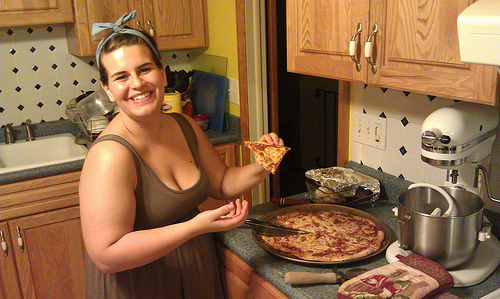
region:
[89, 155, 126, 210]
upper arm on woman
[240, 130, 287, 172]
hand holding the pizza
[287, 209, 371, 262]
part of pizza pie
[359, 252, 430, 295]
an oven mitt on counter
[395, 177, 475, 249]
bottom part of beater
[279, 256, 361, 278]
pizza slicer on counter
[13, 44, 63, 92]
ceramic tile behind sink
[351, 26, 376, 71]
handles on kitchen cabinet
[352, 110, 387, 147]
electrical outlet on wall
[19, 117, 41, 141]
silver faucet on sink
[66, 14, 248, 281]
a woman in a brown dress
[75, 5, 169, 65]
blue hair tie in hair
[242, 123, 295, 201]
one slice of pizza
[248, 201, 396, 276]
a round pan of pizza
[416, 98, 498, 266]
a white mixer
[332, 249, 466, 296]
a decorative oven mitt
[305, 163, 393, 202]
tin foil over container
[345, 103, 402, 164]
white light switches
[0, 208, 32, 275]
white and metal cabinet door pulls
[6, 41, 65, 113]
kitchen wall tiles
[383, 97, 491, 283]
a white mixer on the counter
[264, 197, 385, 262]
a pizza on a pizza pan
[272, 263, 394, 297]
a pizza cutter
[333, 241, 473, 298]
an oven mitt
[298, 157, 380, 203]
a tinfoil covered dish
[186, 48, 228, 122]
cutting boards leaning on a wall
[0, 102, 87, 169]
a white sink in a kitchen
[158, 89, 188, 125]
yellow clorox wipes on a counter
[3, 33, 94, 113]
white with black tile behind a sink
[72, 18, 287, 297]
a woman smiling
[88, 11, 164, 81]
the grey hair tie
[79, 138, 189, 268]
the arm of a woman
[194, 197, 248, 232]
the hand of a woman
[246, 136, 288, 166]
a slice of cheese pizza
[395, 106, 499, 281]
a silver and white blender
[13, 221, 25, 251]
a silver and white handle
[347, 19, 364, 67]
a silver and white handle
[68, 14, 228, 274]
Caucasian woman showing cleavage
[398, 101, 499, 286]
white and shiny chrome mixer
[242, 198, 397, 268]
cheese pizza on round metal pan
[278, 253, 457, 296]
pizza cutter partially covered by potholder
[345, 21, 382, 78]
metal cabinet handles with white trim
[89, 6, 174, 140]
woman wearing blue headband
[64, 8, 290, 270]
woman holding cheese pizza slice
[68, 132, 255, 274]
Caucasian arm bent at elbow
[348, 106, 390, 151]
three light switches on white switchplate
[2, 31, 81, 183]
white sink with black and white diamond backsplash